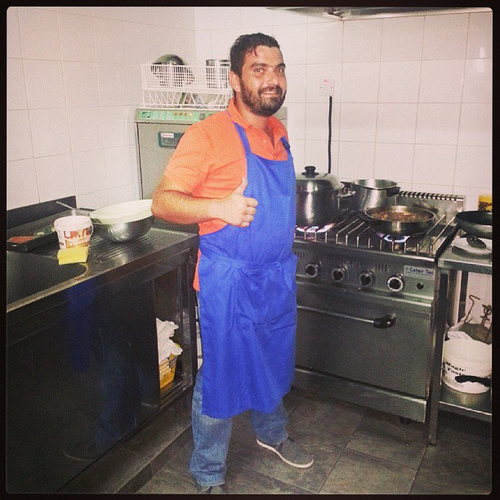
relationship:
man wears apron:
[155, 32, 315, 496] [193, 121, 294, 413]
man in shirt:
[155, 32, 315, 496] [165, 107, 288, 280]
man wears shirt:
[155, 32, 315, 496] [165, 107, 288, 280]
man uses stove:
[155, 32, 315, 496] [294, 167, 464, 435]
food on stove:
[297, 168, 432, 231] [294, 167, 464, 435]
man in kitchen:
[155, 32, 315, 496] [6, 1, 489, 490]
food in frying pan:
[297, 168, 432, 231] [366, 206, 436, 228]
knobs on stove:
[307, 263, 404, 295] [294, 167, 464, 435]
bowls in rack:
[148, 57, 230, 90] [142, 62, 235, 109]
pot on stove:
[294, 165, 340, 223] [294, 167, 464, 435]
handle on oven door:
[298, 307, 397, 330] [297, 290, 435, 403]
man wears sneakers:
[155, 32, 315, 496] [254, 435, 315, 467]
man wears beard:
[155, 32, 315, 496] [243, 86, 288, 112]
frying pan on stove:
[366, 206, 436, 228] [294, 167, 464, 435]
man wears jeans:
[155, 32, 315, 496] [195, 291, 292, 483]